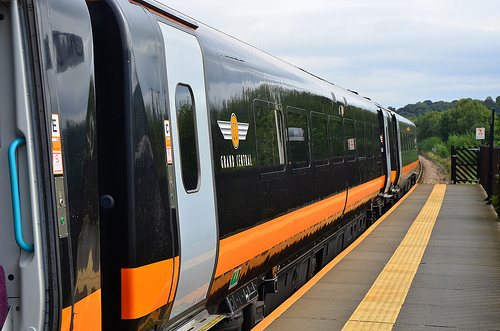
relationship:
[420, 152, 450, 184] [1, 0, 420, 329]
dirt beside train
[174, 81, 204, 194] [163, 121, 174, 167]
window beside sign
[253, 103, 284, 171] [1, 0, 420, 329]
window on train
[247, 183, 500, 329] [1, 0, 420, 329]
loading area reflecting on train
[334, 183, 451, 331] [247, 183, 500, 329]
line part of loading area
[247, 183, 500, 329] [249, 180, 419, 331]
loading area has line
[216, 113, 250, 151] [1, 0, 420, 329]
logo on train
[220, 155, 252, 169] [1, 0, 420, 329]
name on train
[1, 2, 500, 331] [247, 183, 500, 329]
station has loading area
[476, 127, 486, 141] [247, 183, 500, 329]
sign on loading area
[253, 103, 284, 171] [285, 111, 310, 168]
window beside window